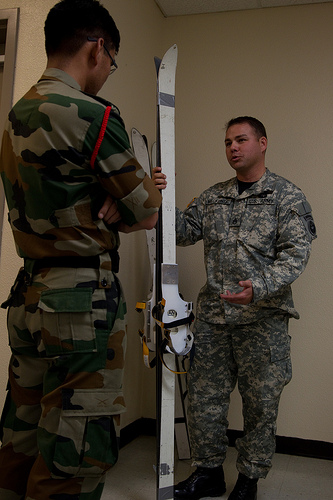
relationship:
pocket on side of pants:
[56, 385, 127, 474] [7, 256, 126, 478]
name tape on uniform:
[204, 195, 231, 205] [179, 167, 318, 465]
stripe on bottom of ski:
[154, 483, 182, 495] [147, 36, 196, 477]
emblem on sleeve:
[306, 216, 319, 240] [251, 190, 312, 303]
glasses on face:
[102, 50, 121, 73] [85, 16, 125, 94]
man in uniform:
[151, 116, 319, 498] [177, 181, 315, 485]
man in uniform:
[0, 0, 163, 499] [5, 64, 159, 444]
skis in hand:
[128, 38, 200, 487] [151, 162, 178, 189]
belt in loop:
[21, 253, 126, 274] [97, 251, 114, 269]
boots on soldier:
[170, 462, 267, 494] [150, 110, 315, 485]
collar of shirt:
[215, 172, 279, 199] [164, 168, 322, 321]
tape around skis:
[153, 88, 180, 106] [128, 38, 200, 487]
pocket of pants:
[36, 280, 101, 361] [7, 256, 126, 478]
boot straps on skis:
[132, 262, 194, 374] [128, 38, 200, 487]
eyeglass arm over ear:
[90, 42, 97, 59] [91, 34, 110, 66]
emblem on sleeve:
[301, 213, 317, 239] [250, 186, 317, 309]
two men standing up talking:
[2, 12, 322, 481] [226, 154, 244, 162]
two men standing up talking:
[2, 12, 322, 481] [226, 153, 245, 162]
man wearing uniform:
[151, 116, 317, 499] [157, 169, 311, 471]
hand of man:
[219, 278, 254, 305] [151, 116, 317, 499]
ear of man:
[89, 34, 104, 64] [0, 0, 162, 495]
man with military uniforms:
[151, 116, 319, 498] [175, 168, 317, 494]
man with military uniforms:
[0, 0, 163, 499] [0, 67, 160, 495]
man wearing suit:
[151, 116, 317, 499] [177, 167, 317, 478]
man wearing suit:
[0, 0, 162, 495] [0, 70, 162, 496]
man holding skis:
[151, 116, 317, 499] [151, 41, 192, 498]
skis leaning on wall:
[136, 44, 198, 499] [2, 2, 162, 448]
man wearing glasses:
[0, 0, 163, 499] [102, 42, 117, 76]